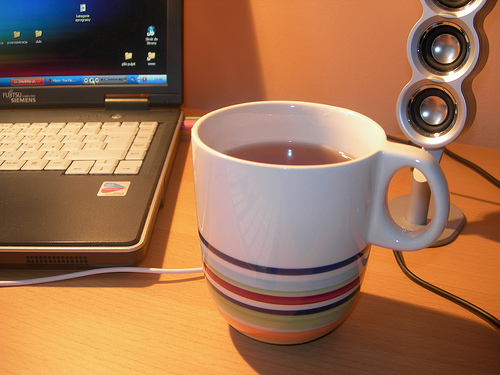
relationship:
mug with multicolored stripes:
[192, 99, 448, 344] [198, 232, 373, 344]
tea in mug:
[224, 143, 348, 163] [192, 99, 448, 344]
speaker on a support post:
[397, 0, 487, 149] [390, 175, 466, 248]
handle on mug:
[375, 140, 451, 251] [192, 99, 448, 344]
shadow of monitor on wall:
[184, 0, 268, 113] [184, 0, 499, 145]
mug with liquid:
[192, 99, 448, 344] [224, 143, 348, 163]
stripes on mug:
[198, 232, 373, 344] [192, 99, 448, 344]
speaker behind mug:
[397, 0, 487, 149] [192, 99, 448, 344]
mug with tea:
[192, 99, 448, 344] [224, 143, 348, 163]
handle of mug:
[375, 140, 451, 251] [192, 99, 448, 344]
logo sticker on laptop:
[96, 180, 131, 197] [0, 0, 184, 265]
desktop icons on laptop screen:
[3, 5, 158, 69] [0, 0, 165, 87]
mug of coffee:
[192, 99, 448, 344] [224, 141, 353, 164]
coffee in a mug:
[224, 141, 353, 164] [192, 99, 448, 344]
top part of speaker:
[423, 0, 489, 15] [397, 0, 487, 149]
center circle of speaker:
[405, 16, 480, 83] [397, 0, 487, 149]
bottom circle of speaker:
[396, 74, 468, 150] [397, 0, 487, 149]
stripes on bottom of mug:
[198, 232, 373, 344] [192, 99, 448, 344]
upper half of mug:
[192, 141, 373, 266] [192, 99, 448, 344]